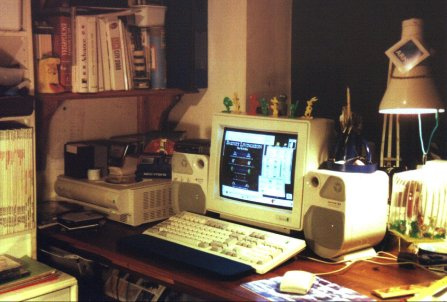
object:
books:
[33, 7, 170, 90]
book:
[72, 12, 85, 92]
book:
[85, 17, 100, 90]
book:
[96, 17, 111, 89]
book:
[105, 17, 128, 88]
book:
[56, 16, 75, 91]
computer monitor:
[206, 112, 311, 232]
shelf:
[36, 86, 198, 149]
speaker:
[300, 159, 390, 264]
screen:
[218, 127, 298, 209]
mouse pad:
[240, 270, 376, 302]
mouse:
[279, 270, 316, 295]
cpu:
[302, 160, 391, 262]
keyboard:
[143, 210, 309, 275]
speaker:
[169, 151, 210, 216]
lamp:
[378, 18, 446, 114]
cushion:
[115, 233, 255, 282]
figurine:
[223, 94, 318, 120]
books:
[58, 14, 136, 91]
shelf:
[29, 0, 211, 96]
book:
[75, 14, 89, 97]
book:
[51, 13, 72, 92]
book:
[87, 13, 97, 92]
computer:
[115, 112, 337, 281]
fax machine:
[54, 174, 172, 226]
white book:
[33, 4, 169, 93]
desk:
[40, 207, 447, 301]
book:
[80, 18, 106, 90]